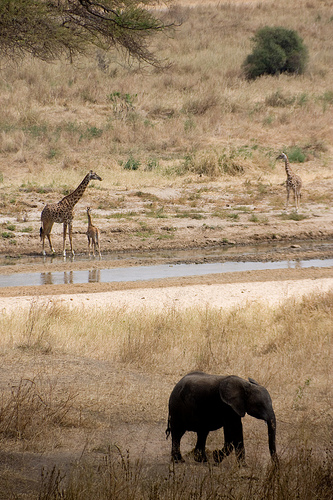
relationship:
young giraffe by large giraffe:
[79, 206, 113, 261] [27, 167, 104, 256]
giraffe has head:
[267, 149, 312, 220] [273, 148, 291, 166]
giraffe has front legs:
[267, 149, 312, 220] [293, 189, 300, 215]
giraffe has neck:
[267, 149, 312, 220] [281, 162, 294, 171]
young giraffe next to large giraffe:
[79, 206, 113, 261] [27, 167, 104, 256]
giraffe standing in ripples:
[267, 149, 312, 220] [0, 257, 333, 288]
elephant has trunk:
[154, 362, 288, 472] [259, 411, 286, 467]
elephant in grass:
[154, 362, 288, 472] [33, 310, 327, 494]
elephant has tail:
[154, 362, 288, 472] [161, 395, 175, 442]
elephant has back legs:
[154, 362, 288, 472] [154, 420, 208, 464]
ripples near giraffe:
[0, 257, 333, 288] [267, 149, 312, 220]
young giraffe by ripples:
[79, 206, 113, 261] [0, 257, 333, 288]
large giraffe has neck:
[27, 167, 104, 256] [70, 180, 85, 202]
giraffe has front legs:
[267, 149, 312, 220] [276, 190, 301, 213]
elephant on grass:
[154, 362, 288, 472] [33, 310, 327, 494]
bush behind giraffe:
[230, 19, 316, 85] [267, 149, 312, 220]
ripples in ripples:
[0, 257, 333, 288] [0, 257, 333, 288]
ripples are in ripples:
[0, 257, 333, 288] [0, 257, 333, 288]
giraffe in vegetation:
[267, 149, 312, 220] [14, 89, 328, 147]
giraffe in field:
[267, 149, 312, 220] [5, 47, 329, 263]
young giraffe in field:
[79, 206, 113, 261] [5, 47, 329, 263]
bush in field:
[230, 19, 316, 85] [5, 47, 329, 263]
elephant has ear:
[154, 362, 288, 472] [209, 375, 247, 417]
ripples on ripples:
[37, 266, 214, 283] [0, 257, 333, 288]